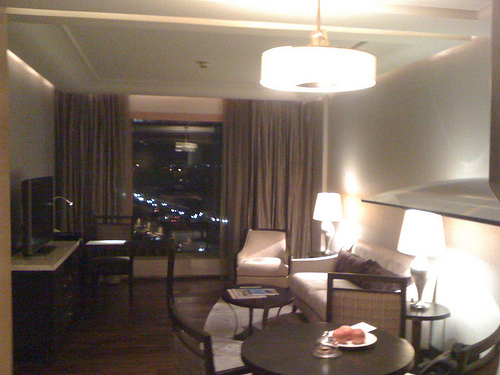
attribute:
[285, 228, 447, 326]
couch — white 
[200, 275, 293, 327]
table — normal